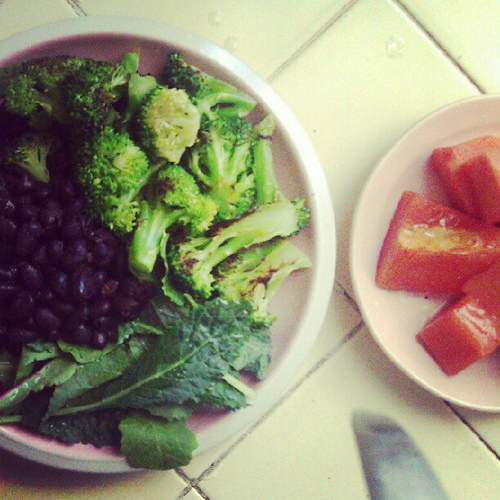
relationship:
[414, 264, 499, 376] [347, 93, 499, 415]
food on bowl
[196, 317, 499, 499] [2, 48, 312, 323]
tile beneath food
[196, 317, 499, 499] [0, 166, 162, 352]
tile beneath food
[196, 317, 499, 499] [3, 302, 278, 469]
tile beneath food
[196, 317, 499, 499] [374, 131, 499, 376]
tile beneath food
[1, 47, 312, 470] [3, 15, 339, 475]
food in bowl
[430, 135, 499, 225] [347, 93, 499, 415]
food on bowl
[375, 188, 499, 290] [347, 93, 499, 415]
food on bowl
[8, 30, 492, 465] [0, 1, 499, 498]
food above tiles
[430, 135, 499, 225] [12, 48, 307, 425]
food near broccoli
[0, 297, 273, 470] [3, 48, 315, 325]
green leaf near broccoli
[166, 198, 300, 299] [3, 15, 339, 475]
food in a bowl